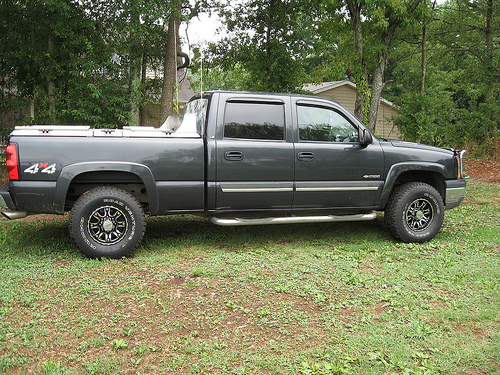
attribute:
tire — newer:
[385, 184, 445, 251]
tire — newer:
[62, 186, 154, 264]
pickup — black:
[1, 83, 392, 220]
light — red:
[5, 145, 18, 180]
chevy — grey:
[7, 86, 470, 261]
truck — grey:
[1, 88, 466, 264]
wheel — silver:
[364, 175, 493, 269]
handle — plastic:
[210, 136, 262, 169]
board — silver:
[218, 204, 403, 234]